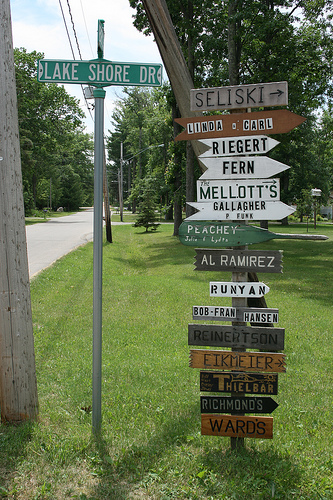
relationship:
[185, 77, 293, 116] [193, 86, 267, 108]
sign for seliski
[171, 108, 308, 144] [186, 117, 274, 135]
sign for linda and carl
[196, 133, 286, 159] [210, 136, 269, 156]
sign for riegert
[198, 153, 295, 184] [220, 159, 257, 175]
sign for fern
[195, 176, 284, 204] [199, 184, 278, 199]
sign for mellott's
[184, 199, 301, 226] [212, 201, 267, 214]
sign for gallagher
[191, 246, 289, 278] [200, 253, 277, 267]
sign for al ramirez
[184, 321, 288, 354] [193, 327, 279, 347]
sign for reinertson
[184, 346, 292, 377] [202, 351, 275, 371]
sign for eikmeier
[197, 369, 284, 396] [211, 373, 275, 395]
sign for thielbar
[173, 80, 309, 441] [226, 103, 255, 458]
signs on pole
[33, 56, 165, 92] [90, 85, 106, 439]
street sign on pole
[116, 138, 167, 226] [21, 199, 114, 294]
streetlight beside road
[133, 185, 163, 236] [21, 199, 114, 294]
pine near road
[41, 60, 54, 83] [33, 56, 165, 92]
letter on sign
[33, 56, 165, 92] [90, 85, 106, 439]
sign on post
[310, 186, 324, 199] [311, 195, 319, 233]
bird house on post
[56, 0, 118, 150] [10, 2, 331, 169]
wires in sky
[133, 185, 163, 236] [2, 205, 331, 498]
tree in grass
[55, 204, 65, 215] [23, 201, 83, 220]
rock on ground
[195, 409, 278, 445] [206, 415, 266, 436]
sign says ward's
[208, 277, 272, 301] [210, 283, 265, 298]
sign says runyan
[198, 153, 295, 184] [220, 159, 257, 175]
sign says fern